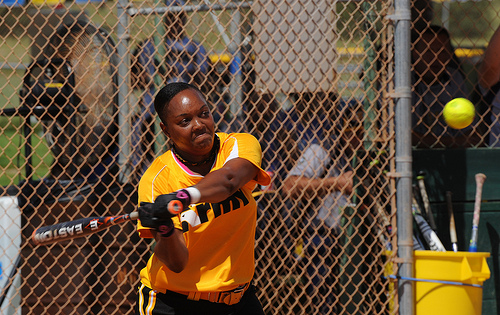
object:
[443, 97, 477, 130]
ball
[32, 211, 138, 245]
bat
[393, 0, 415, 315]
pole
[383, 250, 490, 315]
bucket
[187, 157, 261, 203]
arm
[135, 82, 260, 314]
girl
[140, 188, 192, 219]
glove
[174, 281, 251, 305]
belt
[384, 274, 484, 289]
rope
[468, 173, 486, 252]
bats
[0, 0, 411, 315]
fence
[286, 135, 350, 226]
shirt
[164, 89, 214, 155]
face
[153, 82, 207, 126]
hair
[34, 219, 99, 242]
letters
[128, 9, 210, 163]
people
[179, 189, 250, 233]
letters